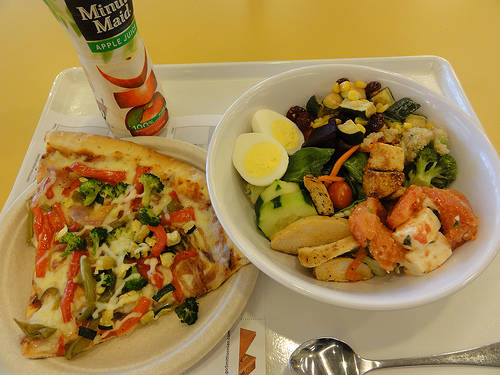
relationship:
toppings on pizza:
[75, 190, 149, 259] [16, 121, 253, 359]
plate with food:
[3, 140, 246, 373] [16, 121, 253, 359]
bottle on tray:
[46, 2, 167, 135] [7, 69, 498, 364]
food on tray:
[263, 106, 441, 262] [7, 69, 498, 364]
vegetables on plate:
[256, 187, 304, 227] [207, 63, 497, 315]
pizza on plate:
[16, 121, 253, 359] [3, 140, 246, 373]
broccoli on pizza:
[61, 232, 111, 259] [16, 121, 253, 359]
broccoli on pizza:
[140, 173, 157, 206] [16, 121, 253, 359]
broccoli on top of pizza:
[96, 268, 150, 293] [16, 121, 253, 359]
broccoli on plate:
[175, 299, 200, 321] [3, 140, 246, 373]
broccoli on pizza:
[80, 180, 101, 202] [16, 121, 253, 359]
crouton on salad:
[364, 143, 406, 168] [263, 106, 441, 262]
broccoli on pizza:
[90, 229, 106, 254] [16, 121, 253, 359]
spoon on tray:
[288, 337, 499, 370] [7, 69, 498, 364]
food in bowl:
[263, 106, 441, 262] [207, 63, 497, 315]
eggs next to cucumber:
[222, 120, 296, 180] [256, 187, 304, 227]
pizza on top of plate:
[16, 121, 253, 359] [3, 140, 246, 373]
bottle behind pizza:
[46, 2, 167, 135] [16, 121, 253, 359]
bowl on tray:
[207, 63, 497, 315] [7, 69, 498, 364]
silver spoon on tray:
[288, 337, 499, 370] [7, 69, 498, 364]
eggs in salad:
[222, 120, 296, 180] [263, 106, 441, 262]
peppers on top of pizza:
[145, 226, 173, 262] [16, 121, 253, 359]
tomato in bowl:
[330, 179, 354, 206] [207, 63, 497, 315]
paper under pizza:
[29, 115, 204, 185] [16, 121, 253, 359]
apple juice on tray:
[46, 2, 167, 135] [7, 69, 498, 364]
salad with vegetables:
[263, 106, 441, 262] [256, 187, 304, 227]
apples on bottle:
[110, 67, 170, 130] [46, 2, 167, 135]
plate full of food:
[3, 130, 262, 373] [16, 121, 253, 359]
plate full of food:
[207, 63, 497, 315] [228, 78, 488, 286]